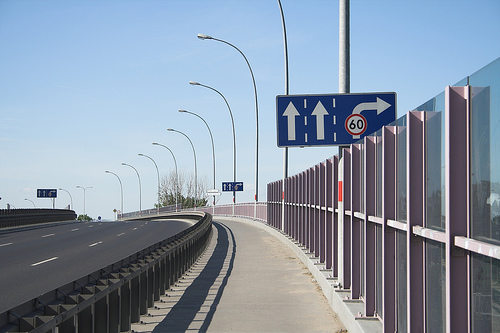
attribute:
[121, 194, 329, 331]
sidewalk — grey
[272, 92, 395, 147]
sign — blue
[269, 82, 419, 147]
arrows — white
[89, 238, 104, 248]
white line — lines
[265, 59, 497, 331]
wall — glass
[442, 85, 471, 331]
beams — metal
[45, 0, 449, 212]
lights — street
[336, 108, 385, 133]
circle — red